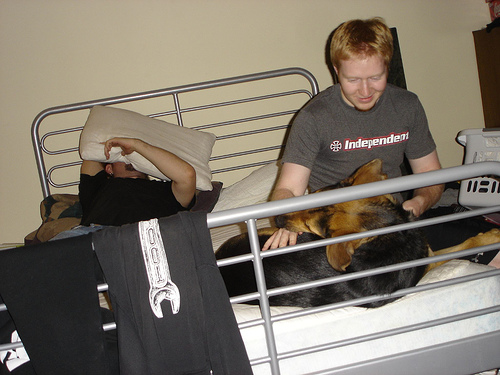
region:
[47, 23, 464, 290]
two guy and a dog on the bed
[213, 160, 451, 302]
a dog on the bed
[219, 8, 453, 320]
a guy petting the dog on the bed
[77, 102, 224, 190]
a pillow the guy is using to cover his face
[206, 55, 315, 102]
a headboard of the bed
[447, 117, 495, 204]
a plastic bin on the bed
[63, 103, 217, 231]
a guy covering his face with a pillow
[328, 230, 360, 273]
an ear of the dog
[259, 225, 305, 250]
a hand of the guy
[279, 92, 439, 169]
a gray shirt the guy is wearing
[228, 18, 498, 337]
man is petting the dog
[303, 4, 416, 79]
man's hair is red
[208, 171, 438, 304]
dog is brown and black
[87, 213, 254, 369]
gray shirt laying on rail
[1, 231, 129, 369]
black shirt laying on rail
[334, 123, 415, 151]
red and white letters on shirt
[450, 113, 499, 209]
white laundry basket on bed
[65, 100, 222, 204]
man holding pillow on face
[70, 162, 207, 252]
man's shirt is black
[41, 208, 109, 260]
man wearing blue jeans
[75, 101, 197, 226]
pillow covering man's face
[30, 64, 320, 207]
metal bed headboard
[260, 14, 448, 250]
man with strawberry blond hair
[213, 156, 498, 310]
dog licking man's hand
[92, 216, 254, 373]
clothing with a silver wrench design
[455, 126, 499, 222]
white plastic laundry basket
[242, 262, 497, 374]
bare mattress on bed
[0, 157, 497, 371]
metallic foot board of bed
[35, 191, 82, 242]
clothing underneath man on bed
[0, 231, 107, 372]
black clothing hung on bedframe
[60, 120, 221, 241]
this is a person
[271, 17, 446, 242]
this is a person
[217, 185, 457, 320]
this is a dog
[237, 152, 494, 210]
a silver rail on the bed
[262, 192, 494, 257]
a silver rail on the bed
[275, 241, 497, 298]
a silver rail on the bed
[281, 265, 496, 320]
a silver rail on the bed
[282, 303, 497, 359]
a silver rail on the bed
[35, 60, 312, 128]
a silver rail on the bed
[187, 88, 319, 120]
a silver rail on the bed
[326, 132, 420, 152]
Independent logo on a gray shirt.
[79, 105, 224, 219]
Man with a pillow over his face.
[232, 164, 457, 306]
Brown and black dog in a bed.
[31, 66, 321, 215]
Headboard made out of silver metal.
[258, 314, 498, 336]
White quilted bed cover with raised design.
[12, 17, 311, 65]
A plain beige empty wall.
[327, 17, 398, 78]
Brown shining man's hair.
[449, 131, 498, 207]
A large white laundry basket.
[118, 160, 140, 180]
A black moustache on a man's face.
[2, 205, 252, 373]
Clothes hanging on a footrail of a bed.